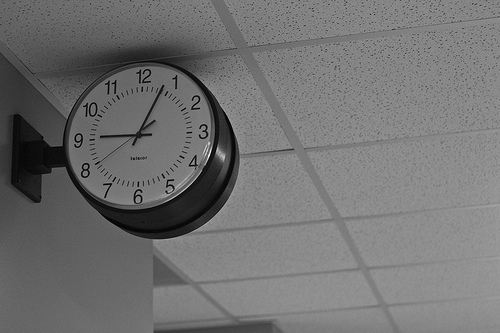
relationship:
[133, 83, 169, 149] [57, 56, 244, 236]
hand on a clock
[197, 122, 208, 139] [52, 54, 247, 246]
number on clock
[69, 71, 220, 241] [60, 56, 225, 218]
number on clock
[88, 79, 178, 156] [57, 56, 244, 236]
hands on clock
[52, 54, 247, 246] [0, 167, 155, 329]
clock on wall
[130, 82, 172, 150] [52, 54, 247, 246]
hand on clock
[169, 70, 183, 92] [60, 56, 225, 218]
one of clock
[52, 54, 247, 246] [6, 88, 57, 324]
clock on wall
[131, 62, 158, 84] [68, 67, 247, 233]
12 on clock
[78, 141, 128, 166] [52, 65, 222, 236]
hand on clock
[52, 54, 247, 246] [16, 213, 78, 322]
clock connected to wall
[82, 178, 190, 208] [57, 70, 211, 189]
numbers around edge of clock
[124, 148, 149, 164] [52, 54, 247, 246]
manufacturer print printed on clock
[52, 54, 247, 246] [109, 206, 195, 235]
clock covered in metal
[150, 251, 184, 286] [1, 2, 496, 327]
lights hung in ceiling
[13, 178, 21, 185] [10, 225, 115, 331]
screw holds metal to wall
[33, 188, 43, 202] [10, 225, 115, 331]
screw holds metal to wall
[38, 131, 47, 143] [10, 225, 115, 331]
screw holds metal to wall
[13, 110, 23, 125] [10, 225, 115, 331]
screw holds metal to wall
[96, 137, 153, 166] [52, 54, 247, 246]
second hand on clock